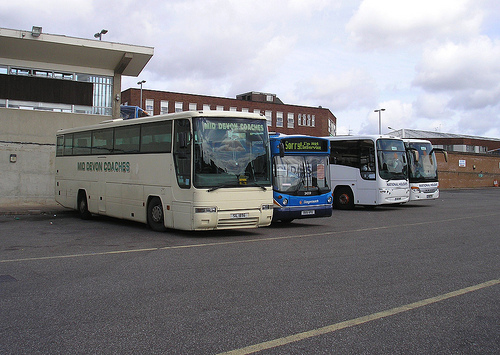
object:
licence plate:
[224, 204, 253, 224]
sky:
[150, 4, 499, 118]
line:
[332, 279, 475, 335]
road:
[215, 241, 498, 348]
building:
[435, 132, 498, 188]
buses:
[48, 97, 446, 247]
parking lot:
[13, 204, 483, 316]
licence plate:
[295, 204, 318, 216]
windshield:
[190, 115, 279, 193]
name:
[72, 155, 135, 178]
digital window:
[272, 132, 339, 155]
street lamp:
[370, 101, 388, 173]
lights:
[88, 23, 117, 39]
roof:
[2, 37, 162, 77]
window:
[50, 117, 177, 162]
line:
[299, 286, 471, 342]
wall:
[448, 152, 486, 186]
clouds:
[410, 35, 499, 102]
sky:
[6, 1, 498, 111]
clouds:
[243, 9, 471, 81]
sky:
[278, 30, 466, 98]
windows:
[49, 115, 186, 160]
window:
[81, 129, 135, 149]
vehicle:
[56, 101, 328, 242]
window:
[273, 164, 338, 204]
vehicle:
[243, 122, 388, 259]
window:
[91, 128, 171, 161]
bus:
[48, 112, 303, 251]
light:
[369, 98, 392, 148]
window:
[135, 117, 178, 155]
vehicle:
[45, 108, 279, 238]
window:
[185, 109, 276, 192]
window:
[170, 114, 194, 187]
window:
[111, 117, 151, 157]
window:
[84, 127, 114, 160]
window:
[62, 132, 73, 155]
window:
[377, 136, 408, 180]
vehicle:
[326, 132, 411, 209]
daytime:
[1, 1, 500, 355]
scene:
[1, 1, 484, 350]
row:
[51, 108, 448, 234]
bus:
[267, 129, 337, 223]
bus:
[328, 130, 420, 208]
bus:
[403, 137, 450, 203]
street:
[1, 186, 483, 352]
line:
[215, 280, 485, 352]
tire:
[75, 189, 90, 219]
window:
[112, 124, 141, 154]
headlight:
[194, 205, 216, 213]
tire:
[146, 196, 165, 230]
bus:
[45, 106, 285, 255]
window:
[131, 108, 188, 162]